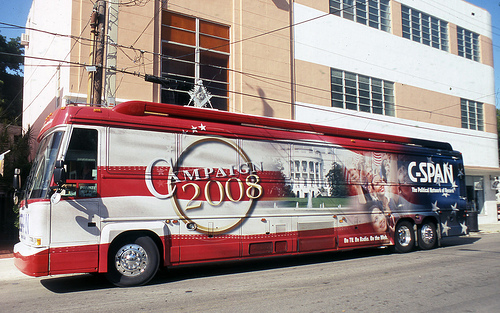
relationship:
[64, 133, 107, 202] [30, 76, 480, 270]
window on a bus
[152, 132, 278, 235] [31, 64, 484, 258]
circle sitting on bus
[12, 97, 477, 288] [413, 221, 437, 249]
bus on tire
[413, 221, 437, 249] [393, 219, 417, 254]
tire on tire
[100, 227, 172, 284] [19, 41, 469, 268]
tire on a bus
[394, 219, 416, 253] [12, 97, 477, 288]
tire on a bus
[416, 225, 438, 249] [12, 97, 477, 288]
tire on a bus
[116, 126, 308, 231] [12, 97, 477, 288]
sign on a bus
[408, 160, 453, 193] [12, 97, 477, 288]
sign on bus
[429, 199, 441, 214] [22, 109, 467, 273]
star on bus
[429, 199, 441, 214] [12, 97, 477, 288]
star on bus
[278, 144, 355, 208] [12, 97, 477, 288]
image on bus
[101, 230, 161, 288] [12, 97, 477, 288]
tire on bus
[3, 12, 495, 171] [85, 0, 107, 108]
wires on pole